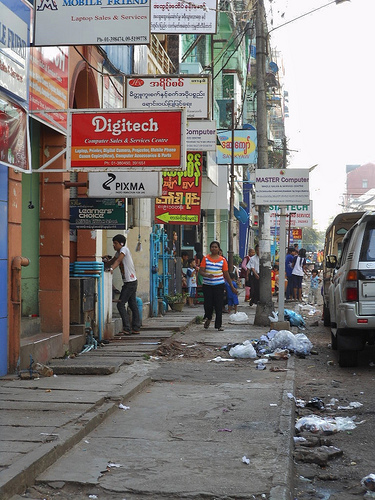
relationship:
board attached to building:
[66, 107, 187, 171] [1, 1, 283, 376]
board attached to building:
[124, 73, 212, 122] [1, 1, 283, 376]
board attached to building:
[34, 0, 151, 46] [1, 1, 283, 376]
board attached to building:
[68, 197, 126, 232] [1, 1, 283, 376]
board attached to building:
[153, 151, 201, 222] [1, 1, 283, 376]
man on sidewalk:
[107, 234, 140, 336] [1, 290, 299, 498]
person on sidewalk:
[197, 242, 238, 331] [1, 290, 299, 498]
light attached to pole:
[269, 1, 351, 40] [252, 0, 274, 325]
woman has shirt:
[197, 242, 238, 331] [199, 254, 226, 287]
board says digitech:
[66, 106, 187, 172] [91, 116, 158, 134]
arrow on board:
[153, 211, 197, 225] [154, 150, 203, 225]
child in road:
[306, 268, 320, 306] [297, 269, 374, 498]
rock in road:
[295, 435, 341, 471] [297, 269, 374, 498]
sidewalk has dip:
[1, 290, 299, 498] [162, 337, 228, 368]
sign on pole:
[253, 168, 308, 208] [273, 207, 290, 334]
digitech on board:
[91, 116, 158, 134] [66, 106, 187, 172]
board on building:
[66, 106, 187, 172] [1, 1, 283, 376]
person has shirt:
[197, 242, 238, 331] [199, 254, 226, 287]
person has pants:
[197, 242, 238, 331] [202, 284, 224, 330]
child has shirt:
[306, 268, 320, 306] [310, 277, 320, 287]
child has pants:
[306, 268, 320, 306] [308, 288, 319, 304]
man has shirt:
[104, 234, 141, 335] [115, 249, 137, 281]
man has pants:
[104, 234, 141, 335] [116, 281, 141, 332]